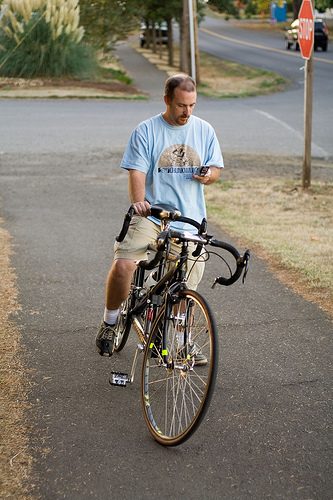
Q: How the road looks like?
A: Smooth.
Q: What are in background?
A: Trees.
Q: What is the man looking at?
A: A phone.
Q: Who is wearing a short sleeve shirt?
A: A man.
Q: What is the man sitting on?
A: A bike.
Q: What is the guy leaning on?
A: A bike.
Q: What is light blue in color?
A: The man's shirt.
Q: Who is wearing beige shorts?
A: The man.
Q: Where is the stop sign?
A: On the street corner.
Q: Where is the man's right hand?
A: On the handlebar.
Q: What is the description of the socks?
A: White socks.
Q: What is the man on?
A: A bicycle.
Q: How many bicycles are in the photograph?
A: One.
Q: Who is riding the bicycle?
A: A man.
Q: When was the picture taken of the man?
A: Daytime.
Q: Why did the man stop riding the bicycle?
A: To look at the cellphone.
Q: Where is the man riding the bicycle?
A: The street.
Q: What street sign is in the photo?
A: Stop.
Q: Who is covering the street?
A: Asphalt.